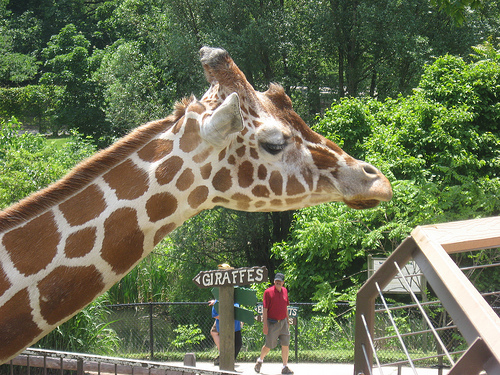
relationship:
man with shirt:
[184, 283, 267, 354] [211, 287, 243, 322]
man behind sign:
[208, 299, 243, 367] [187, 265, 281, 344]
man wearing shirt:
[255, 273, 294, 375] [260, 284, 289, 321]